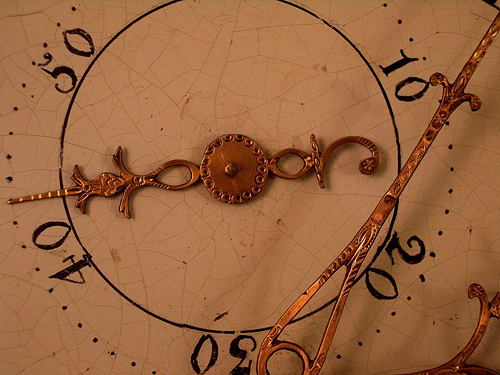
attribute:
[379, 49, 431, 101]
10 — black, printed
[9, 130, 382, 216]
dial — partial, brass, golf, golden, pointy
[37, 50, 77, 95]
number — black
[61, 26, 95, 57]
number — black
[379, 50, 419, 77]
number — black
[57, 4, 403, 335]
circle — black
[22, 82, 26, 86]
dot — minute, black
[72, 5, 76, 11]
dot — black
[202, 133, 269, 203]
circle — reflective, middle, gold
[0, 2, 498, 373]
background — cracked, marble, tan, antique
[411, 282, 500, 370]
decoration — gold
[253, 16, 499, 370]
dial — golden, partial, brass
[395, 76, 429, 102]
number — black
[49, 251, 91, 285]
number — black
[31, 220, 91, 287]
40 — black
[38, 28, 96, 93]
50 — black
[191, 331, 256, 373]
30 — black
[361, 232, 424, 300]
20 — black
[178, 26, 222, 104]
crack — small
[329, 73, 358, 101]
crack — small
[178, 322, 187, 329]
protuberance — little